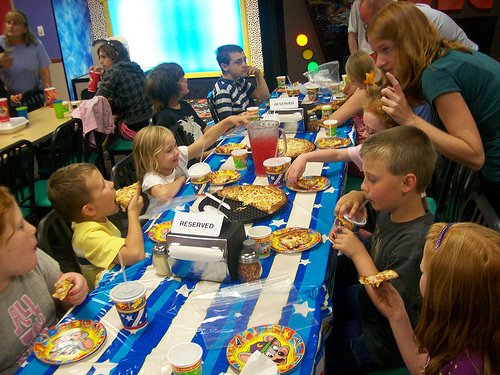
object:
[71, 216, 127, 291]
shirt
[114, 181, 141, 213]
pizza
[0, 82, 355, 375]
tablecloth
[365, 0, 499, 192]
adult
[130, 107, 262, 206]
child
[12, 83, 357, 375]
table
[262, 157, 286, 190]
cup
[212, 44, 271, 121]
boy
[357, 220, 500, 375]
child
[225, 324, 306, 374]
plate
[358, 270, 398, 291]
pizza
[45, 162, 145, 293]
boy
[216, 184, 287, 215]
pizza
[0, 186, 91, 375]
kids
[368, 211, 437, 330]
shirt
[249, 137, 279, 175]
drink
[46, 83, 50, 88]
straw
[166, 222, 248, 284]
dispenser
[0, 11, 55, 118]
people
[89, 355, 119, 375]
stars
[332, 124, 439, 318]
boy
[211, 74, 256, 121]
shirt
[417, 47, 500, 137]
shirt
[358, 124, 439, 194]
hair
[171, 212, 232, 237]
sign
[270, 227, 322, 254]
plate